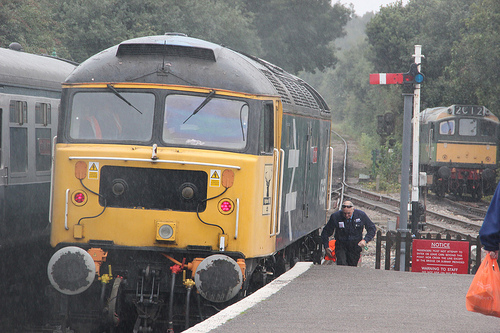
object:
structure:
[468, 251, 499, 323]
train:
[411, 104, 500, 201]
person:
[478, 181, 499, 260]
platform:
[183, 262, 499, 332]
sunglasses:
[342, 205, 354, 209]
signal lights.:
[405, 68, 425, 85]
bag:
[465, 253, 500, 319]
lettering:
[416, 243, 465, 275]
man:
[321, 201, 377, 267]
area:
[307, 39, 436, 211]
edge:
[179, 253, 305, 332]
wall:
[281, 177, 326, 204]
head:
[342, 201, 355, 219]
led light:
[217, 197, 236, 215]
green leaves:
[446, 20, 478, 56]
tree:
[364, 0, 500, 108]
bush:
[355, 92, 403, 141]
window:
[69, 92, 155, 142]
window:
[162, 93, 249, 150]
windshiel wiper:
[106, 83, 143, 114]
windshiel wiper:
[183, 90, 216, 124]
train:
[0, 42, 80, 333]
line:
[176, 262, 314, 333]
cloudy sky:
[327, 0, 410, 17]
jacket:
[321, 209, 377, 249]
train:
[45, 31, 334, 332]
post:
[409, 41, 424, 208]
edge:
[51, 145, 98, 247]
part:
[443, 58, 474, 89]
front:
[39, 25, 289, 327]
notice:
[411, 239, 469, 276]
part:
[441, 238, 466, 273]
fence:
[375, 229, 482, 275]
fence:
[364, 223, 484, 285]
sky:
[302, 2, 438, 48]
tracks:
[333, 125, 492, 248]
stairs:
[310, 258, 370, 272]